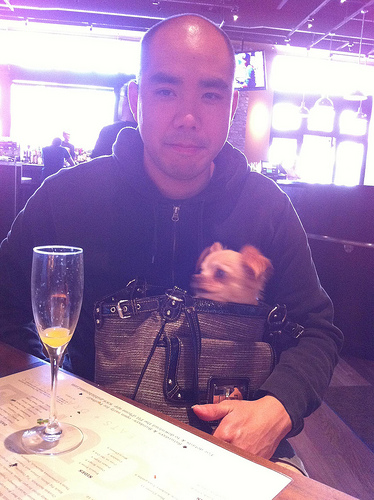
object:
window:
[6, 72, 134, 162]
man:
[0, 8, 345, 481]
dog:
[191, 241, 275, 305]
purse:
[93, 275, 304, 435]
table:
[0, 341, 360, 500]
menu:
[0, 365, 292, 500]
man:
[41, 137, 76, 180]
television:
[234, 49, 267, 93]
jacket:
[0, 126, 343, 437]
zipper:
[168, 205, 181, 278]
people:
[89, 79, 138, 163]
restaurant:
[2, 1, 374, 500]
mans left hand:
[191, 396, 295, 459]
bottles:
[20, 145, 41, 164]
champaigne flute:
[20, 245, 83, 455]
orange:
[37, 326, 73, 349]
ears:
[239, 244, 274, 281]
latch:
[96, 296, 160, 320]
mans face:
[136, 15, 233, 180]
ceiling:
[236, 2, 373, 49]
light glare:
[264, 48, 374, 191]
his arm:
[263, 204, 341, 438]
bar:
[1, 131, 42, 167]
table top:
[274, 465, 354, 499]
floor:
[305, 403, 372, 481]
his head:
[135, 13, 236, 177]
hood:
[113, 126, 142, 172]